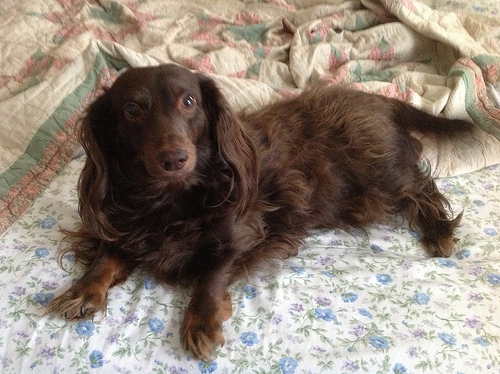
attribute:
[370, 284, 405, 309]
leaves — green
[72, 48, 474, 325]
dog — relaxing, laying, brown, black, furry, small, sitting, Dark , little , young, looking, tiny, chilling, scared, cute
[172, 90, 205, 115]
eye — brown, small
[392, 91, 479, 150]
tail — short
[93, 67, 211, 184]
face — long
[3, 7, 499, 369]
bed — big, white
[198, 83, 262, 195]
ear — brown, long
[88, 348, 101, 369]
flower — blue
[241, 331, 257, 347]
flower — blue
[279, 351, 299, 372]
flower — blue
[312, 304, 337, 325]
flower — blue, purple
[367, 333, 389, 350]
flower — blue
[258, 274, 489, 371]
sheet — white, purple, flat, new